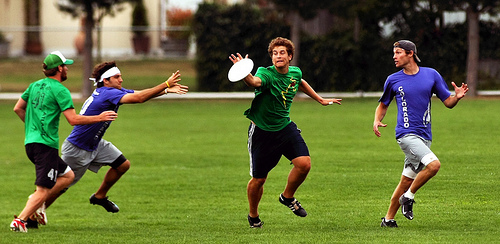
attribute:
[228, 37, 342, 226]
man — reaching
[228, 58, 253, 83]
frisbee — white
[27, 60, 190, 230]
man — diving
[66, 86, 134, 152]
shirt — blue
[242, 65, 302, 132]
shirt — green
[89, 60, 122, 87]
head band — white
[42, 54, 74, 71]
hat — green, white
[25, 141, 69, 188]
shorts — black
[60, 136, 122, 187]
shorts — grey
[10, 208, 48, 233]
shoes — red, white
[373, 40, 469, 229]
man — playing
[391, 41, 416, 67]
head — turned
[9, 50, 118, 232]
man — playing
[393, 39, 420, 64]
hat — backwards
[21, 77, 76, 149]
shirt — green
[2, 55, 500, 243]
grass — green